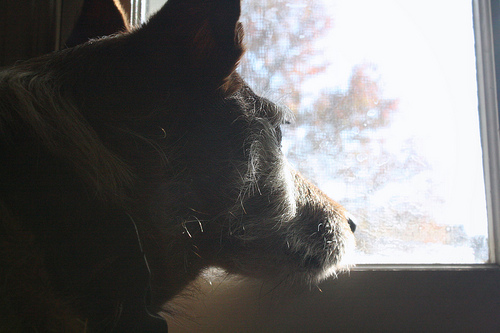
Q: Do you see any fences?
A: No, there are no fences.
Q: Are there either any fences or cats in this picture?
A: No, there are no fences or cats.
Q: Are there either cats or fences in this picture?
A: No, there are no fences or cats.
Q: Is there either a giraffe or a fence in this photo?
A: No, there are no fences or giraffes.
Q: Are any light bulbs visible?
A: No, there are no light bulbs.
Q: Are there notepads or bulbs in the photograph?
A: No, there are no bulbs or notepads.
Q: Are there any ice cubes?
A: No, there are no ice cubes.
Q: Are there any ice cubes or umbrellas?
A: No, there are no ice cubes or umbrellas.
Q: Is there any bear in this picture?
A: No, there are no bears.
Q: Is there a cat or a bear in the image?
A: No, there are no bears or cats.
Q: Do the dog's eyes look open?
A: Yes, the eyes are open.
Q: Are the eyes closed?
A: No, the eyes are open.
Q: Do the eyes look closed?
A: No, the eyes are open.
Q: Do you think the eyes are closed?
A: No, the eyes are open.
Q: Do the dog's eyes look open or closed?
A: The eyes are open.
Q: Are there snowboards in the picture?
A: No, there are no snowboards.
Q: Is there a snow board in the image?
A: No, there are no snowboards.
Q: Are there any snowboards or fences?
A: No, there are no snowboards or fences.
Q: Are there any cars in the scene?
A: No, there are no cars.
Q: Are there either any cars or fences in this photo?
A: No, there are no cars or fences.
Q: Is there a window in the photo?
A: Yes, there is a window.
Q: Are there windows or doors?
A: Yes, there is a window.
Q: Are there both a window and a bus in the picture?
A: No, there is a window but no buses.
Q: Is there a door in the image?
A: No, there are no doors.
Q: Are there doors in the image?
A: No, there are no doors.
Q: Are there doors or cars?
A: No, there are no doors or cars.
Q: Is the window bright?
A: Yes, the window is bright.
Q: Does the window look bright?
A: Yes, the window is bright.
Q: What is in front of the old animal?
A: The window is in front of the dog.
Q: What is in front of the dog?
A: The window is in front of the dog.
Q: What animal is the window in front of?
A: The window is in front of the dog.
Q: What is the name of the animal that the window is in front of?
A: The animal is a dog.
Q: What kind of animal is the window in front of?
A: The window is in front of the dog.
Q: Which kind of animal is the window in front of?
A: The window is in front of the dog.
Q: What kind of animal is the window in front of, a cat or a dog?
A: The window is in front of a dog.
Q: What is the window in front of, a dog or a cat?
A: The window is in front of a dog.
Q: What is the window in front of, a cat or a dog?
A: The window is in front of a dog.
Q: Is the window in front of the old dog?
A: Yes, the window is in front of the dog.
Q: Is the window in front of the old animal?
A: Yes, the window is in front of the dog.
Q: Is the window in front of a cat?
A: No, the window is in front of the dog.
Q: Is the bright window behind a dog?
A: No, the window is in front of a dog.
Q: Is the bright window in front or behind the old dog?
A: The window is in front of the dog.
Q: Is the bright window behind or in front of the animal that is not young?
A: The window is in front of the dog.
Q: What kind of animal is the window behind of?
A: The window is behind the dog.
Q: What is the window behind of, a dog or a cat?
A: The window is behind a dog.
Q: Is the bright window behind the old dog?
A: Yes, the window is behind the dog.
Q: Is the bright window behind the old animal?
A: Yes, the window is behind the dog.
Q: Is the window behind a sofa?
A: No, the window is behind the dog.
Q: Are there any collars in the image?
A: Yes, there is a collar.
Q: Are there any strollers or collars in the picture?
A: Yes, there is a collar.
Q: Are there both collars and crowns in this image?
A: No, there is a collar but no crowns.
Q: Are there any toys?
A: No, there are no toys.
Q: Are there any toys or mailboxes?
A: No, there are no toys or mailboxes.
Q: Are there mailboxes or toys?
A: No, there are no toys or mailboxes.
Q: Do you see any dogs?
A: Yes, there is a dog.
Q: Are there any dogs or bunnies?
A: Yes, there is a dog.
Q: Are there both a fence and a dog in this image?
A: No, there is a dog but no fences.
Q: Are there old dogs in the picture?
A: Yes, there is an old dog.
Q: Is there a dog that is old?
A: Yes, there is a dog that is old.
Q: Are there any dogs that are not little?
A: Yes, there is a old dog.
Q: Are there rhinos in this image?
A: No, there are no rhinos.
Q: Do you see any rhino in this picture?
A: No, there are no rhinos.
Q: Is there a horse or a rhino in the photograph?
A: No, there are no rhinos or horses.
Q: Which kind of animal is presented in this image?
A: The animal is a dog.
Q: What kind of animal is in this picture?
A: The animal is a dog.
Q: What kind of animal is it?
A: The animal is a dog.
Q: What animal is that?
A: This is a dog.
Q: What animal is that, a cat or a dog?
A: This is a dog.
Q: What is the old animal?
A: The animal is a dog.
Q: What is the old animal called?
A: The animal is a dog.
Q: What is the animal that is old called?
A: The animal is a dog.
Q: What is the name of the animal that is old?
A: The animal is a dog.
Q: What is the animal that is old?
A: The animal is a dog.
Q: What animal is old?
A: The animal is a dog.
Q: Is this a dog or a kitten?
A: This is a dog.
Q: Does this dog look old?
A: Yes, the dog is old.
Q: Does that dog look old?
A: Yes, the dog is old.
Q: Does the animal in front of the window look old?
A: Yes, the dog is old.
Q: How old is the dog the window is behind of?
A: The dog is old.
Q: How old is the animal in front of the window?
A: The dog is old.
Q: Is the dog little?
A: No, the dog is old.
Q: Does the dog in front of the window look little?
A: No, the dog is old.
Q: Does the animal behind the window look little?
A: No, the dog is old.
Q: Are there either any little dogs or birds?
A: No, there is a dog but it is old.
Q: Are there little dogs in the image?
A: No, there is a dog but it is old.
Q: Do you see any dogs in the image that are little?
A: No, there is a dog but it is old.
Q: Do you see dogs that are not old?
A: No, there is a dog but it is old.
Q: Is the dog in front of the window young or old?
A: The dog is old.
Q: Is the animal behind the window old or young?
A: The dog is old.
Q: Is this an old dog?
A: Yes, this is an old dog.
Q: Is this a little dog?
A: No, this is an old dog.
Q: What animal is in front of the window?
A: The dog is in front of the window.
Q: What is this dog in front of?
A: The dog is in front of the window.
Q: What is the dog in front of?
A: The dog is in front of the window.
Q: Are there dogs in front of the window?
A: Yes, there is a dog in front of the window.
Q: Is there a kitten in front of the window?
A: No, there is a dog in front of the window.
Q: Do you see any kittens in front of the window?
A: No, there is a dog in front of the window.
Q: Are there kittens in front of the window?
A: No, there is a dog in front of the window.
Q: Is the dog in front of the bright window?
A: Yes, the dog is in front of the window.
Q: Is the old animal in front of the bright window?
A: Yes, the dog is in front of the window.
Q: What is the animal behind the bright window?
A: The animal is a dog.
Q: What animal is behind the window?
A: The animal is a dog.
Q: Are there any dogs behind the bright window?
A: Yes, there is a dog behind the window.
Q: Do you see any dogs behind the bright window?
A: Yes, there is a dog behind the window.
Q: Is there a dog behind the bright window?
A: Yes, there is a dog behind the window.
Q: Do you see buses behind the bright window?
A: No, there is a dog behind the window.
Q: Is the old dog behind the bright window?
A: Yes, the dog is behind the window.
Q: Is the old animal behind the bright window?
A: Yes, the dog is behind the window.